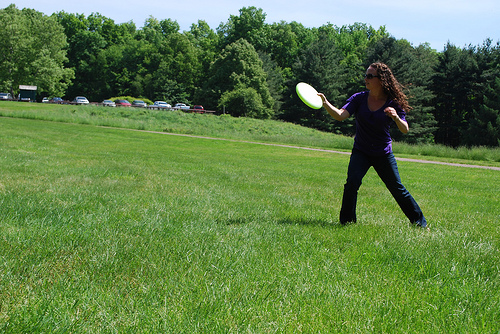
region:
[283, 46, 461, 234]
the girl is playing frisbee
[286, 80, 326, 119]
the frisbee is white or maybe green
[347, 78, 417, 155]
the girl is wearing a purple shirt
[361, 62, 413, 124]
he lady has curly hair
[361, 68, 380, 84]
the lady is wearing sunglasses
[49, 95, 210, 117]
many cars are parked in the lot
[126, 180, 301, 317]
the grass is ankle deep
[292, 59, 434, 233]
a woman is holding a frisbee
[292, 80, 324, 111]
frisbee is yellow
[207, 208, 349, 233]
shadow in the grass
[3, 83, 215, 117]
cars in a parking lot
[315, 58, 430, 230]
woman has long dark curly hair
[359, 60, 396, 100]
woman is wearing sunglasses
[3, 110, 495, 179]
a pathway in a park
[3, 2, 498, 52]
blue cloudless sky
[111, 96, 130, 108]
a red car in a parking lot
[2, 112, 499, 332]
lush green grass in a park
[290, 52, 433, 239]
A woman playing frisbee in a park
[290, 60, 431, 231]
A woman playing frisbee in a park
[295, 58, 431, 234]
A woman playing frisbee in a park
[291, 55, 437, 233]
A woman playing frisbee in a park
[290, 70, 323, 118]
The frisbee is green.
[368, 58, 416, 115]
The woman's hair is dark.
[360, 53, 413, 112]
The woman's hair is long.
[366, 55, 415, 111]
The woman's hair is curly.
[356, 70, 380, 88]
The woman is wearing dark glasses.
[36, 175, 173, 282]
The grass is green.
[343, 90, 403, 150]
The woman's shirt is purple.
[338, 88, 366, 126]
The shirt has short sleeves.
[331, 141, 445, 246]
The woman's pants are blue.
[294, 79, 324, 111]
Woman holding a frisbee.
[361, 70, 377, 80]
Woman wearing sunglasses.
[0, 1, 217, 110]
Trees behind the cars.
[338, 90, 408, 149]
woman wearing a purple shirt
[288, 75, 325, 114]
woman holding a green frisbee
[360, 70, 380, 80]
woman wearing black sunglasses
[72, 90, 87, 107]
car parked in the lot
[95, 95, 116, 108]
car parked in the lot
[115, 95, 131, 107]
car parked in the lot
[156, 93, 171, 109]
car parked in the lot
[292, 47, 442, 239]
woman standing in the grass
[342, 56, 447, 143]
girl has long hair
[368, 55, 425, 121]
girl has brown hair